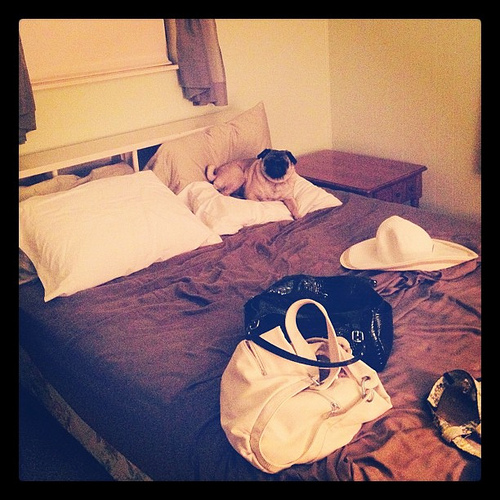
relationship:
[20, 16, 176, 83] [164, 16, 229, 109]
window has curtain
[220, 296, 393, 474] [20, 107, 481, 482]
bags on bed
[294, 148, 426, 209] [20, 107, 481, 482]
table beside bed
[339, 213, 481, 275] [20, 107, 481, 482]
hat on bed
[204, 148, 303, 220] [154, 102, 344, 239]
pug on pillow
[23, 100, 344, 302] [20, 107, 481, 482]
pillows on bed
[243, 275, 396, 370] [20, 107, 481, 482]
purse on bed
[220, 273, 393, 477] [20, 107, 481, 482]
bags on bed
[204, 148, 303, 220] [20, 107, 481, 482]
pug on bed